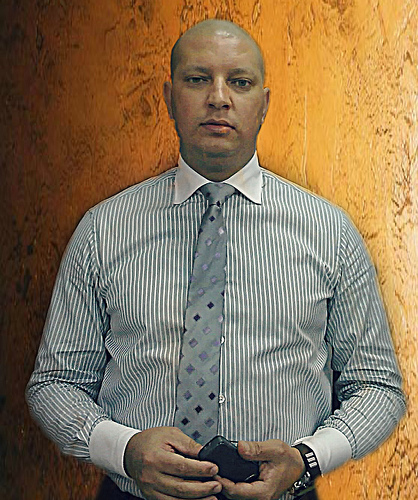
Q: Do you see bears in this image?
A: No, there are no bears.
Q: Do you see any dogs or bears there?
A: No, there are no bears or dogs.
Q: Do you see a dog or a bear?
A: No, there are no bears or dogs.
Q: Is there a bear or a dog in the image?
A: No, there are no bears or dogs.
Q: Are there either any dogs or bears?
A: No, there are no bears or dogs.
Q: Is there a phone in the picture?
A: Yes, there is a phone.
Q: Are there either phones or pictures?
A: Yes, there is a phone.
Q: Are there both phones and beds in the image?
A: No, there is a phone but no beds.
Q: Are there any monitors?
A: No, there are no monitors.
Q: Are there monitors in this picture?
A: No, there are no monitors.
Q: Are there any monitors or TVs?
A: No, there are no monitors or tvs.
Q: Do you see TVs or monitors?
A: No, there are no monitors or tvs.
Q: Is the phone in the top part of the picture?
A: No, the phone is in the bottom of the image.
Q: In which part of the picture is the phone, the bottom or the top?
A: The phone is in the bottom of the image.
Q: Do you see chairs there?
A: No, there are no chairs.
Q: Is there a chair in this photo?
A: No, there are no chairs.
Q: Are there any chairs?
A: No, there are no chairs.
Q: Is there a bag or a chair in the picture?
A: No, there are no chairs or bags.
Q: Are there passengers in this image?
A: No, there are no passengers.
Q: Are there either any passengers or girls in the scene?
A: No, there are no passengers or girls.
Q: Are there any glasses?
A: No, there are no glasses.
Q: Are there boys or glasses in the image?
A: No, there are no glasses or boys.